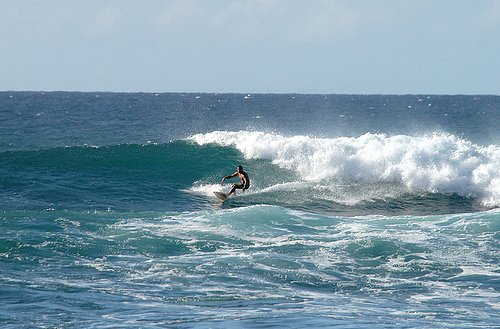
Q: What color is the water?
A: Blue and white.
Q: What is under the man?
A: The surfboard.